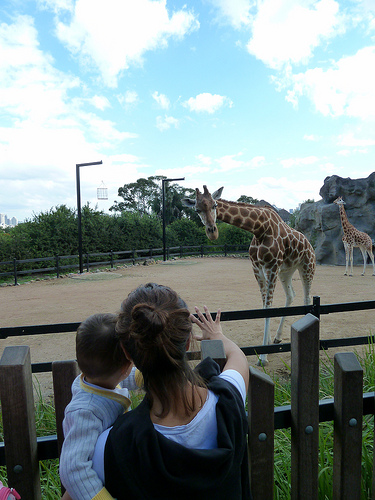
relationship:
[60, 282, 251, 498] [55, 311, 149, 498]
woman holding baby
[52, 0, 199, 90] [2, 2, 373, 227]
cloud in sky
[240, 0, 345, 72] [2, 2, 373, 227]
cloud in sky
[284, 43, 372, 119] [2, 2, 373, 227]
cloud in sky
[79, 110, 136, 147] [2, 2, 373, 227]
cloud in sky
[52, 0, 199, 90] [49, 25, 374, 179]
cloud in sky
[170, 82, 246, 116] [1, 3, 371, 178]
cloud in sky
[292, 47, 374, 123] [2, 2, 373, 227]
cloud in sky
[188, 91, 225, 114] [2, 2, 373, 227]
cloud in sky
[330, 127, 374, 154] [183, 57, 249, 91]
white cloud in blue sky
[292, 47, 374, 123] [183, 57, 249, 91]
cloud in blue sky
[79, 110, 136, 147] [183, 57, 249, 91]
cloud in blue sky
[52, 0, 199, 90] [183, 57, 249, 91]
cloud in blue sky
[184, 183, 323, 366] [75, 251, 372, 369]
giraffe standing on ground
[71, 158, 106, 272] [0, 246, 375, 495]
pole in ground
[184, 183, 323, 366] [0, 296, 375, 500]
giraffe in fence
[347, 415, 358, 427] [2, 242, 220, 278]
bolts on fence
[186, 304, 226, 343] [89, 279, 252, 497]
hand belonging to woman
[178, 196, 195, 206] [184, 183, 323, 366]
ear belonging to giraffe